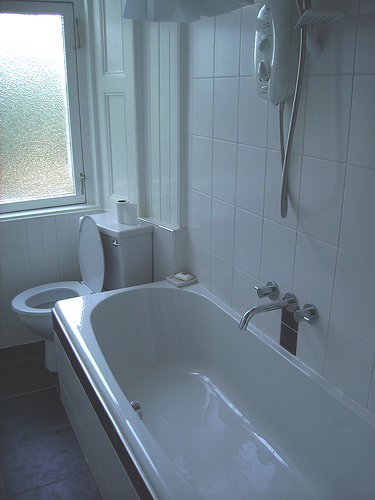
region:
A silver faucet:
[241, 302, 288, 333]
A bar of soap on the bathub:
[170, 270, 193, 286]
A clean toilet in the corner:
[0, 217, 101, 305]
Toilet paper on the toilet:
[113, 196, 145, 226]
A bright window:
[3, 18, 84, 199]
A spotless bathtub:
[117, 327, 265, 480]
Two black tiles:
[271, 301, 305, 359]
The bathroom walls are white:
[188, 44, 260, 249]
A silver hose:
[272, 91, 314, 222]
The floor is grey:
[0, 372, 71, 483]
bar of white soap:
[172, 263, 196, 281]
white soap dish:
[163, 265, 204, 291]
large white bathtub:
[37, 253, 367, 498]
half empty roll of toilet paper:
[107, 188, 143, 228]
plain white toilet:
[12, 191, 170, 389]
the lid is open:
[9, 201, 112, 327]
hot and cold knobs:
[223, 258, 326, 371]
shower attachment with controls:
[245, 6, 352, 234]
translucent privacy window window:
[2, 3, 93, 216]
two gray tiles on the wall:
[261, 277, 311, 375]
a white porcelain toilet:
[13, 214, 104, 367]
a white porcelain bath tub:
[51, 267, 374, 498]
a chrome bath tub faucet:
[240, 278, 312, 346]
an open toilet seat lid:
[73, 213, 106, 294]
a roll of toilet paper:
[113, 196, 140, 228]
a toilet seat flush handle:
[109, 237, 119, 248]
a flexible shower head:
[250, 2, 312, 215]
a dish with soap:
[165, 267, 192, 288]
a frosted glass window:
[2, 14, 88, 203]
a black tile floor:
[0, 334, 96, 499]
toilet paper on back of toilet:
[112, 194, 143, 224]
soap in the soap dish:
[166, 261, 215, 299]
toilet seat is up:
[31, 216, 114, 292]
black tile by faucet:
[260, 287, 326, 357]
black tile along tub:
[57, 329, 147, 496]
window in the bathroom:
[23, 20, 97, 198]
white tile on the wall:
[213, 120, 311, 277]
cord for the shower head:
[275, 32, 322, 215]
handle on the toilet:
[111, 232, 142, 255]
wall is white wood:
[95, 43, 155, 157]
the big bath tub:
[50, 271, 368, 498]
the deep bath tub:
[60, 281, 372, 495]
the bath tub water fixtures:
[237, 282, 319, 338]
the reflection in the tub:
[182, 358, 300, 487]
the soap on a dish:
[175, 270, 190, 280]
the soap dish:
[165, 271, 195, 288]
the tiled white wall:
[186, 128, 270, 267]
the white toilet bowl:
[12, 210, 154, 369]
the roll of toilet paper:
[114, 199, 138, 223]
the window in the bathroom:
[1, 1, 88, 214]